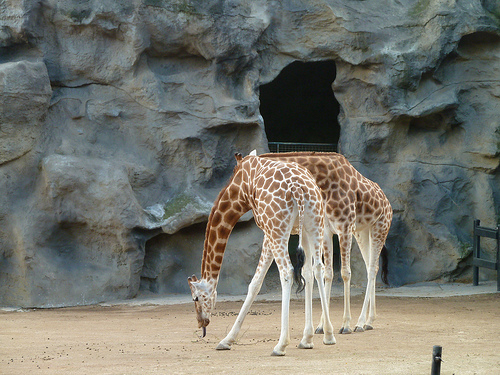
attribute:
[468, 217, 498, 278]
fence —    black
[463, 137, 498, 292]
gate — metal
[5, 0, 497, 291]
cliffs —  rocky, rocky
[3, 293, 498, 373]
floor —  with sandy consistency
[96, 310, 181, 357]
ground — brown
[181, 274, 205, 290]
ears —   two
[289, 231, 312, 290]
tail — black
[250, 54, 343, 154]
big hole —  Big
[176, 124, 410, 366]
two giraffes —  two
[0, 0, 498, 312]
rocky wall —   rocky  ,  concrete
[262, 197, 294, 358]
tall legs —   tall 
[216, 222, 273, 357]
tall legs —   tall 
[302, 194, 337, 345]
tall legs —   tall 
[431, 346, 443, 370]
pole —  fence's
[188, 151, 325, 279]
spots — brown